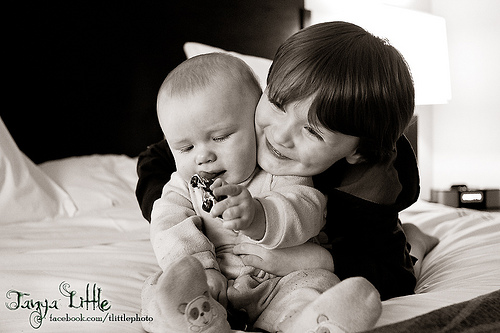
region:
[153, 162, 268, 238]
the baby is holding a toy car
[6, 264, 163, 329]
the signature shows this is a professional photograph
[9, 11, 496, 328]
the photo is in black and white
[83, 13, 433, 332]
the two boys in the picture are most likely brothers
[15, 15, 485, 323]
the boys are sitting on the bed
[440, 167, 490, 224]
there is a clock present in the background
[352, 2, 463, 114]
the lamp in the background is on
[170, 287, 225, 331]
the baby has a panda bear on his feet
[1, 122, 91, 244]
a portion of the pillow for the bed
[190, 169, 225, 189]
the baby is sticking their tongue out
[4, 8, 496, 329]
Black and white photo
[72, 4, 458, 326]
Two children in the photo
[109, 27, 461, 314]
Two kids on a bed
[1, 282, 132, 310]
Photo by Tanya Little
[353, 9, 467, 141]
Lamp turned on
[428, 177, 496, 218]
Alarm clock on the night table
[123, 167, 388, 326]
Pajamas on the baby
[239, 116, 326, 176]
The boy is smiling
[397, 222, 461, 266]
The boy is barefoot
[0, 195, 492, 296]
The sheets are white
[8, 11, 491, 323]
Black and white color.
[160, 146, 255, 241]
Baby is holding the car.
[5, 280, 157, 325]
Letters are black color.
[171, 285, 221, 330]
Teddy bear face is in foot.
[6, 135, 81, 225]
One pillow is in bed.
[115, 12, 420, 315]
Two children are in bed.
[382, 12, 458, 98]
Light is in the corner of the room.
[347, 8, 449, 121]
Light is behind the children.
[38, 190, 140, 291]
Bed sheet is white color.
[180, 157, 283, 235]
Baby is holding the car in left hand.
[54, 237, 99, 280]
White sheets on the bed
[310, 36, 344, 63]
Brown hair of little boy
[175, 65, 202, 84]
Hair of the infant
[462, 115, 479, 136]
Small part of white wall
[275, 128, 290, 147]
Nose of little boy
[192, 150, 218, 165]
Nose of the infant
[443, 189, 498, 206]
Black and gray clock in the background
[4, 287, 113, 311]
Name of the person who sponsored the photo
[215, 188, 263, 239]
Left hand of baby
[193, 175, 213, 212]
Toy that the baby is holding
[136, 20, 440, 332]
the children on the bed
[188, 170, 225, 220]
the toy in the baby's hand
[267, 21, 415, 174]
the hair on the boy's head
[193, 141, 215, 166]
the nose on the baby's face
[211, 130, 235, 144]
the eye on the baby's face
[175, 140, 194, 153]
the eye on the baby's face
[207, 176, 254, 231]
the baby's small hand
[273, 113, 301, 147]
the nose on the baby's face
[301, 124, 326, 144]
the eye on the boy's face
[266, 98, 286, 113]
the eye on the boy's face